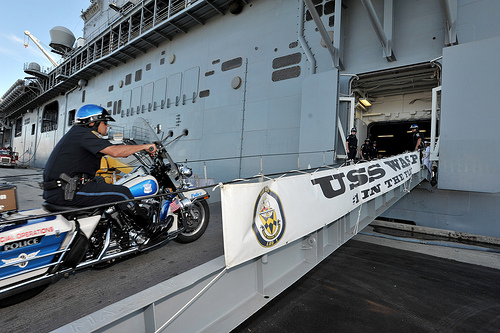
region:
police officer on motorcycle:
[41, 88, 238, 322]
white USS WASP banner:
[207, 130, 455, 234]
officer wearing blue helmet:
[53, 93, 144, 173]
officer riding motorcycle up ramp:
[54, 85, 280, 291]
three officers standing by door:
[333, 70, 448, 190]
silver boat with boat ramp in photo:
[11, 28, 451, 208]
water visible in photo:
[276, 261, 493, 330]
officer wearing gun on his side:
[46, 146, 120, 206]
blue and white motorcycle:
[11, 171, 239, 253]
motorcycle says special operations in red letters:
[2, 211, 98, 284]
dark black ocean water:
[363, 267, 425, 321]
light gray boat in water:
[126, 31, 381, 134]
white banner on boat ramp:
[210, 168, 454, 237]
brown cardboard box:
[7, 181, 33, 214]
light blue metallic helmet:
[76, 102, 120, 140]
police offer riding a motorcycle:
[57, 129, 180, 248]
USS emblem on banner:
[221, 182, 303, 264]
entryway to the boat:
[353, 74, 423, 169]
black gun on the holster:
[49, 172, 87, 215]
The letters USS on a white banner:
[305, 161, 405, 197]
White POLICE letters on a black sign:
[1, 231, 56, 252]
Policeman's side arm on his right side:
[53, 171, 81, 203]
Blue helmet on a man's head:
[73, 100, 117, 124]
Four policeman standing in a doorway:
[343, 72, 438, 161]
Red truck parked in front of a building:
[0, 136, 22, 172]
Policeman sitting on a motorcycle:
[37, 103, 217, 255]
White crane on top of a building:
[18, 25, 60, 79]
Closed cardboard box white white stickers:
[0, 179, 20, 215]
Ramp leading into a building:
[7, 159, 439, 330]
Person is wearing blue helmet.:
[68, 93, 133, 152]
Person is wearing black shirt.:
[46, 125, 116, 199]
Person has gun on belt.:
[58, 167, 91, 232]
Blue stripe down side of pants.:
[79, 187, 156, 227]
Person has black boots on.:
[147, 213, 194, 251]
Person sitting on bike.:
[14, 129, 158, 251]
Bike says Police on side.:
[5, 231, 85, 286]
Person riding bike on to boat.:
[6, 105, 285, 229]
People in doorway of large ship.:
[332, 105, 472, 182]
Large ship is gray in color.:
[166, 2, 420, 161]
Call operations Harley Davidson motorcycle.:
[3, 92, 214, 289]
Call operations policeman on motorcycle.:
[31, 94, 170, 279]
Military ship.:
[3, 0, 498, 180]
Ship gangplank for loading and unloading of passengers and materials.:
[1, 114, 471, 314]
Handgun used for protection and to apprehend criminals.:
[51, 163, 94, 212]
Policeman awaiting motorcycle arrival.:
[343, 108, 435, 170]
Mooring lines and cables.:
[128, 107, 206, 170]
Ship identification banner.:
[224, 145, 452, 222]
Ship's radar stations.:
[8, 7, 103, 87]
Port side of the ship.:
[11, 0, 485, 272]